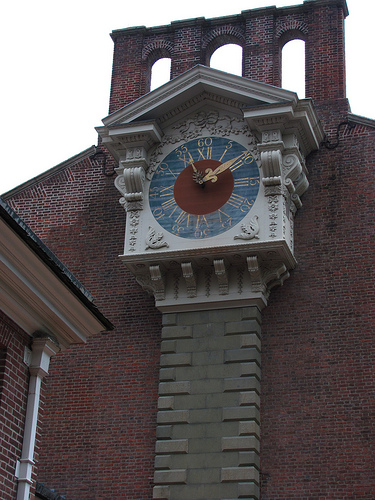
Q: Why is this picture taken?
A: Photography.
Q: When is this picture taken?
A: 11:10.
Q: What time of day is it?
A: Afternoon.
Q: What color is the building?
A: Brick.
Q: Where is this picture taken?
A: Below building.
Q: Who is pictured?
A: None.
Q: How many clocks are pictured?
A: One.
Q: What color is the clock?
A: Blue and burgundy and white.